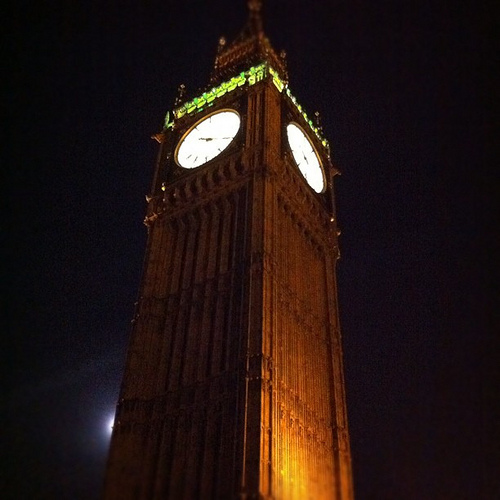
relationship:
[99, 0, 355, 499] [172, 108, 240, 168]
tower has clock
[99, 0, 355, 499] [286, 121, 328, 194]
tower has clock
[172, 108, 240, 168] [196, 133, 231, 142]
clock has hands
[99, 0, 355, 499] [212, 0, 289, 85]
tower has tip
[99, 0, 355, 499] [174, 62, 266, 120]
tower has lights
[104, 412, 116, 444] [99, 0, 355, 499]
moon behind tower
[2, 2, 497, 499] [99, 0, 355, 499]
sky behind tower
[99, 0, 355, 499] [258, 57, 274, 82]
tower has corner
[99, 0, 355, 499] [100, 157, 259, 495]
tower has wall